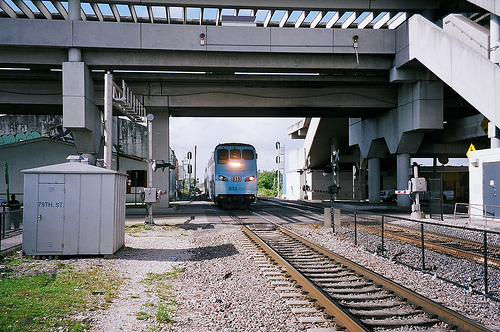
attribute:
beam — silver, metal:
[293, 3, 311, 26]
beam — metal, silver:
[275, 9, 292, 26]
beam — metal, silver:
[258, 10, 278, 25]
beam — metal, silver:
[176, 6, 190, 22]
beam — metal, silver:
[158, 6, 173, 21]